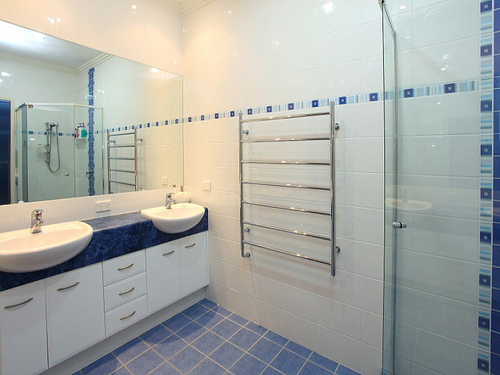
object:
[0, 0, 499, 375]
bathroom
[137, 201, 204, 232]
sink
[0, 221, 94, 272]
sink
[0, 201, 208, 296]
counter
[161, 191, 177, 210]
faucet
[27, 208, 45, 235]
faucet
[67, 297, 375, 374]
tile floor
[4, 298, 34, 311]
handles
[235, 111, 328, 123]
towel rack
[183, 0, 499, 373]
wall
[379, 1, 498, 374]
shower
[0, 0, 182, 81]
wall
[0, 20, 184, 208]
mirror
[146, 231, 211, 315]
cabinet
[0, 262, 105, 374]
cabinet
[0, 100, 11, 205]
door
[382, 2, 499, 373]
walls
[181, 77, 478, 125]
accent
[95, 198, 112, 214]
outlet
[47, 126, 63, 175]
hose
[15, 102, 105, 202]
shower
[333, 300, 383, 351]
tile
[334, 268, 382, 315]
tile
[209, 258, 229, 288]
tile